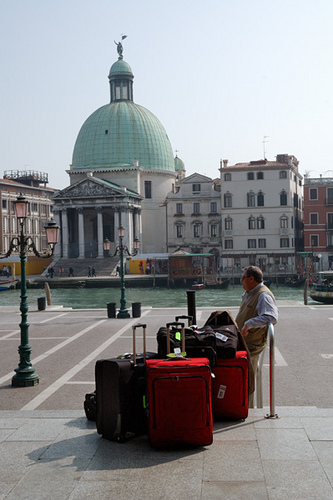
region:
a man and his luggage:
[22, 236, 304, 447]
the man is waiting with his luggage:
[87, 267, 296, 443]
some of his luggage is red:
[151, 346, 258, 458]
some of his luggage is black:
[78, 324, 149, 447]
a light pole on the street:
[7, 180, 44, 397]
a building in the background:
[51, 180, 131, 285]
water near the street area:
[37, 279, 234, 305]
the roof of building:
[75, 29, 190, 185]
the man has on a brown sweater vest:
[228, 264, 279, 351]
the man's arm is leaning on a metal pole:
[242, 303, 290, 419]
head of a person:
[237, 259, 277, 296]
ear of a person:
[248, 273, 260, 282]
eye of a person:
[240, 271, 249, 279]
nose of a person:
[236, 275, 246, 285]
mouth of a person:
[239, 279, 251, 289]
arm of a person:
[260, 294, 281, 333]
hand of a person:
[238, 317, 254, 335]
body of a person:
[223, 283, 285, 353]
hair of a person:
[251, 266, 264, 273]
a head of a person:
[232, 259, 269, 301]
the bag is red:
[150, 354, 214, 451]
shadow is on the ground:
[37, 422, 149, 486]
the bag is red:
[214, 355, 252, 421]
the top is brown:
[231, 288, 278, 352]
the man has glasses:
[232, 266, 289, 416]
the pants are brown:
[250, 355, 264, 416]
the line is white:
[58, 325, 120, 343]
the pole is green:
[8, 246, 42, 384]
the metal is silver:
[266, 321, 278, 418]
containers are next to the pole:
[102, 301, 143, 318]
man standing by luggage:
[222, 252, 295, 422]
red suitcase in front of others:
[137, 328, 222, 462]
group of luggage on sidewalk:
[74, 292, 253, 455]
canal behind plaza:
[72, 254, 310, 325]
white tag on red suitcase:
[210, 367, 243, 410]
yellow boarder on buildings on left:
[2, 234, 50, 283]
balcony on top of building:
[2, 153, 57, 201]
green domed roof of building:
[69, 19, 191, 191]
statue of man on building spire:
[97, 27, 146, 102]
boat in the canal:
[303, 252, 332, 313]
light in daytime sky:
[0, 1, 331, 183]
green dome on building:
[53, 101, 174, 273]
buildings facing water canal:
[3, 163, 330, 306]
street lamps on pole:
[1, 193, 60, 384]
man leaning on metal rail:
[234, 266, 276, 417]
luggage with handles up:
[85, 312, 249, 449]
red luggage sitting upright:
[144, 357, 212, 448]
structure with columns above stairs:
[48, 177, 139, 277]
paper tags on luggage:
[168, 323, 229, 398]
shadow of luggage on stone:
[27, 434, 193, 471]